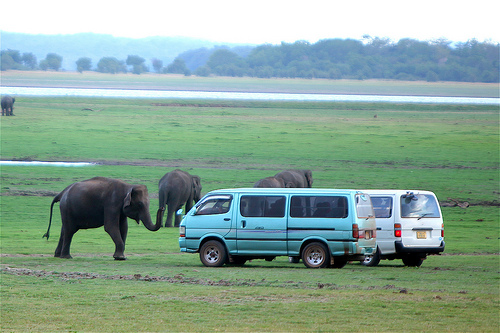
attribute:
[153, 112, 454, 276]
van — blue, white, wheel, side, parked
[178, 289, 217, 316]
grass — short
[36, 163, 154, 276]
elephant — tail, trunk, several, standing, head, leg, walking, up, group, body, eye, ear, mouth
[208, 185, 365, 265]
vehicle — parked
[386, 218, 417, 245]
light — red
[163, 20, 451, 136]
tree — back, leave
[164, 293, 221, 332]
ground — green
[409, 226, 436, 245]
plate — license, yellow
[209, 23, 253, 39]
sky — white